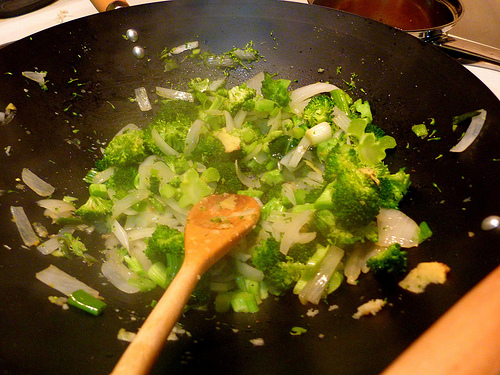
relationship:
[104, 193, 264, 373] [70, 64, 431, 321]
spoon in food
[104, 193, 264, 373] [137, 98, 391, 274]
spoon in food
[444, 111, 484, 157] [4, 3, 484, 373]
onion on side of skillet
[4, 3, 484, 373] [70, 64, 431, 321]
skillet full of food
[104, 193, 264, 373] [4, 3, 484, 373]
spoon sitting in skillet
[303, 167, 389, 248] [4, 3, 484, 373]
broccoli in skillet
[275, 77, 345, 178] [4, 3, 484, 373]
onions in skillet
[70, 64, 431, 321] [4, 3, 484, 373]
food cooking in skillet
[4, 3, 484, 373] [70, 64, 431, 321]
skillet of food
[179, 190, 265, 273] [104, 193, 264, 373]
head of spoon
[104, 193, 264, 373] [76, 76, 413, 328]
spoon in food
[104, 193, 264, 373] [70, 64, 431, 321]
spoon stirring food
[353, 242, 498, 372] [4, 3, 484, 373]
table next to skillet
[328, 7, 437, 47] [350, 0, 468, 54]
sauce in a pan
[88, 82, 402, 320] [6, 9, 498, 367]
broccoli in a pan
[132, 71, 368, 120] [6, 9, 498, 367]
onions in a pan